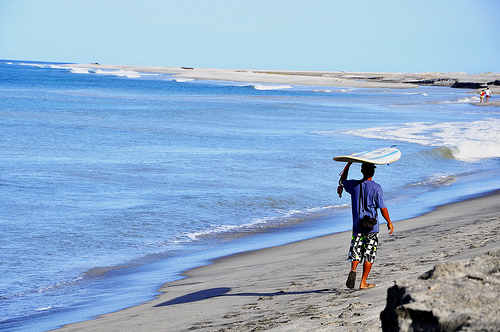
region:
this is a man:
[332, 154, 400, 285]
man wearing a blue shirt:
[331, 182, 397, 227]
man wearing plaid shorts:
[343, 222, 383, 264]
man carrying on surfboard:
[325, 120, 408, 290]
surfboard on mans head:
[318, 134, 413, 196]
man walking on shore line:
[71, 127, 428, 302]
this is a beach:
[236, 227, 460, 324]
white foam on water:
[365, 102, 497, 174]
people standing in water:
[457, 75, 496, 120]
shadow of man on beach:
[139, 234, 316, 319]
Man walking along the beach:
[322, 135, 396, 298]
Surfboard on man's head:
[329, 133, 401, 170]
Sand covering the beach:
[37, 180, 498, 330]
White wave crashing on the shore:
[387, 96, 499, 181]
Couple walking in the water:
[472, 80, 492, 111]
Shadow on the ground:
[155, 280, 332, 306]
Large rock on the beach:
[383, 210, 499, 322]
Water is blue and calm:
[2, 72, 496, 329]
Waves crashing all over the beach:
[36, 56, 425, 103]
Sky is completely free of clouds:
[1, 16, 493, 76]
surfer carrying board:
[324, 122, 415, 279]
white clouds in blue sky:
[200, 22, 238, 42]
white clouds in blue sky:
[362, 16, 407, 50]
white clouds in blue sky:
[435, 25, 477, 63]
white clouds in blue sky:
[358, 22, 419, 66]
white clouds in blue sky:
[292, 11, 340, 39]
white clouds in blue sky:
[242, 8, 279, 45]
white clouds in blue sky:
[207, 8, 268, 38]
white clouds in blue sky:
[134, 26, 178, 51]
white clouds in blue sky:
[71, 19, 141, 49]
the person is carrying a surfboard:
[314, 108, 421, 312]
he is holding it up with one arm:
[320, 133, 435, 328]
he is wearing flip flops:
[330, 244, 400, 314]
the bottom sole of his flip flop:
[337, 253, 360, 299]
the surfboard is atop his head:
[315, 122, 425, 169]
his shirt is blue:
[333, 173, 400, 238]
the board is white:
[312, 129, 433, 171]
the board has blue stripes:
[317, 119, 426, 168]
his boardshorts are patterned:
[336, 222, 386, 269]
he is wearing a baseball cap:
[354, 155, 398, 171]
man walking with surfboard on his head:
[332, 139, 402, 294]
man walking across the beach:
[17, 156, 492, 326]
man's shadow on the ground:
[145, 275, 335, 305]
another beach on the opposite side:
[85, 50, 495, 80]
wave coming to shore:
[55, 65, 435, 110]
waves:
[50, 68, 312, 104]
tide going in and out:
[12, 165, 488, 296]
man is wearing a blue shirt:
[337, 155, 393, 288]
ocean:
[3, 61, 459, 271]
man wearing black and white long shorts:
[342, 220, 377, 268]